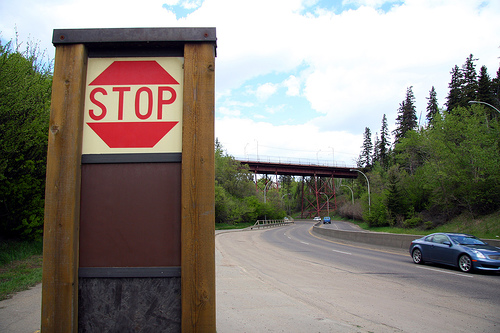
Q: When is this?
A: Daytime.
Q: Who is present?
A: No one.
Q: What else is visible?
A: Trees.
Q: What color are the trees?
A: Green.